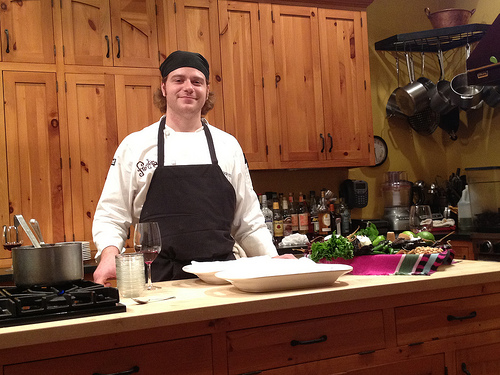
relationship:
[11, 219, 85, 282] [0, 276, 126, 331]
pot sitting on stove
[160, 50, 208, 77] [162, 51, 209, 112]
bandana placed on man's head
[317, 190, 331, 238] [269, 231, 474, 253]
bottle sitting on counter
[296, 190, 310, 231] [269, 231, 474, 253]
bottle sitting on counter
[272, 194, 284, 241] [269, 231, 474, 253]
bottle sitting on counter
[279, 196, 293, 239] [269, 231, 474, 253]
bottle sitting on counter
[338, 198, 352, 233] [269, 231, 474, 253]
bottle sitting on counter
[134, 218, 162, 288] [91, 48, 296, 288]
glass of wine in front of man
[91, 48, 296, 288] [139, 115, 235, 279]
man with apron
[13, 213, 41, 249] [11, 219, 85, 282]
spoon inside pot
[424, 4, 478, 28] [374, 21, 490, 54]
cooking ware sitting on rack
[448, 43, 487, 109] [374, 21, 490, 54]
pot hanging on rack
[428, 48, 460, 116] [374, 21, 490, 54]
pot hanging on rack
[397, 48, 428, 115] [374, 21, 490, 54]
pot hanging on rack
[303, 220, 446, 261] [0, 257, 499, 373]
fresh vegetables sitting on table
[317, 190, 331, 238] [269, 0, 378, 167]
bottle under cabinet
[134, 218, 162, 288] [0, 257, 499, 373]
glass of wine sitting on table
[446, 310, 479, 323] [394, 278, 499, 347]
handle attached to drawer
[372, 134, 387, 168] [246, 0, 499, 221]
clock hanging on wall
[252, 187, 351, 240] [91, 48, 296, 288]
group of bottles right of man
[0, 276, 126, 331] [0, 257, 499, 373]
stove sitting on table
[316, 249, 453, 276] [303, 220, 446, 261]
tray full of fresh vegetables